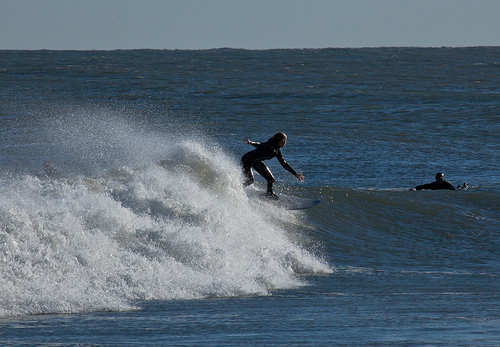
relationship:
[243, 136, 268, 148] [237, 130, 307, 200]
right arm of person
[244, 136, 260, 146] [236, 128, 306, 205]
left arm of person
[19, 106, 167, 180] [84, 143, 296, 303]
spray from wave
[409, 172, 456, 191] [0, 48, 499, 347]
man in water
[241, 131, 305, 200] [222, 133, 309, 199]
person wearing wetsuit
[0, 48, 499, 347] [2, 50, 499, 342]
water in sea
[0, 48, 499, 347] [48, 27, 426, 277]
water in sea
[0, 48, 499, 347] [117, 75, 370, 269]
water in sea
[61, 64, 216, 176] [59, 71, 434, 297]
water in sea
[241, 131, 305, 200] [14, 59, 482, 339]
person surfing in water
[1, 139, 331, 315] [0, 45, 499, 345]
white wave in ocean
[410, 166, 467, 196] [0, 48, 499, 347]
man in water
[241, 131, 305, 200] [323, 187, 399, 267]
person riding a wave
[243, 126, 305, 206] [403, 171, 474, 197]
person on a person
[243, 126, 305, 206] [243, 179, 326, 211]
person on a surfboard